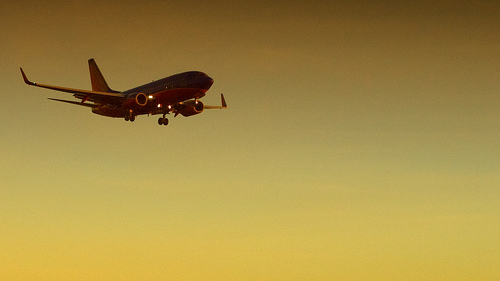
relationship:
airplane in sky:
[17, 41, 234, 135] [10, 8, 499, 269]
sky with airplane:
[10, 8, 499, 269] [17, 41, 234, 135]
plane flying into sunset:
[17, 41, 234, 135] [12, 174, 498, 269]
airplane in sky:
[20, 58, 228, 127] [10, 8, 499, 269]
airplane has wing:
[20, 58, 228, 127] [18, 62, 125, 100]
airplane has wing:
[20, 58, 228, 127] [205, 89, 230, 115]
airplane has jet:
[20, 58, 228, 127] [126, 87, 154, 111]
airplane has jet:
[20, 58, 228, 127] [179, 99, 204, 118]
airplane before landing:
[20, 58, 228, 127] [4, 164, 499, 275]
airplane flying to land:
[20, 58, 228, 127] [6, 150, 498, 277]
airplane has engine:
[20, 58, 228, 127] [122, 90, 147, 109]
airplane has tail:
[20, 58, 228, 127] [85, 54, 107, 88]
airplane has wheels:
[20, 58, 228, 127] [120, 108, 170, 129]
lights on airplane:
[141, 87, 200, 118] [20, 58, 228, 127]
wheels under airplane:
[120, 108, 170, 129] [20, 58, 228, 127]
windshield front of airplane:
[189, 72, 205, 80] [20, 58, 228, 127]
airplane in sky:
[20, 58, 228, 127] [0, 0, 500, 281]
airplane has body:
[20, 58, 228, 127] [122, 67, 214, 107]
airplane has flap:
[20, 58, 228, 127] [44, 96, 114, 109]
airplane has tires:
[20, 58, 228, 127] [119, 108, 136, 122]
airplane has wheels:
[20, 58, 228, 127] [158, 117, 169, 125]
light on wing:
[33, 78, 38, 86] [18, 62, 125, 100]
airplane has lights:
[20, 58, 228, 127] [141, 87, 200, 118]